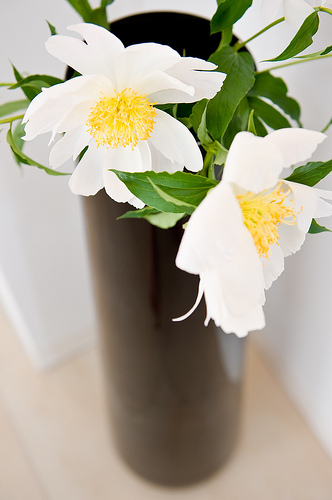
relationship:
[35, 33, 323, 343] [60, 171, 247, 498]
flowers in vase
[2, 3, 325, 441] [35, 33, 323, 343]
wall behind flowers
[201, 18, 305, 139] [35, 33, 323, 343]
leaves surrounding flowers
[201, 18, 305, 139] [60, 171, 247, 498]
leaves in a vase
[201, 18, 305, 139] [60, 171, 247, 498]
leaves in vase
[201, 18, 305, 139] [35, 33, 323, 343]
leaves above flowers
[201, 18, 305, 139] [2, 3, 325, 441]
leaves near wall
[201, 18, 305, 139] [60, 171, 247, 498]
leaves inside vase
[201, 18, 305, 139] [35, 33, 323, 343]
leaves touching flowers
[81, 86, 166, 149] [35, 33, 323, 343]
stamens in flowers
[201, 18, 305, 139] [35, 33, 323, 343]
leaves between flowers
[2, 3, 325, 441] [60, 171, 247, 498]
wall underneath vase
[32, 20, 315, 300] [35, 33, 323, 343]
petals on flowers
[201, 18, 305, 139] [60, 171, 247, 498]
leaves on right of vase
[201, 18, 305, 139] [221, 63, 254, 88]
leaves colored green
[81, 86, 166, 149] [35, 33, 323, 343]
stamens in center of flowers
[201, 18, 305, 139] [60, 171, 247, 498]
leaves inside of vase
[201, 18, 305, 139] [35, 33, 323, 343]
leaves behind flowers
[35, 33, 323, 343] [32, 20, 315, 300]
flowers have petals